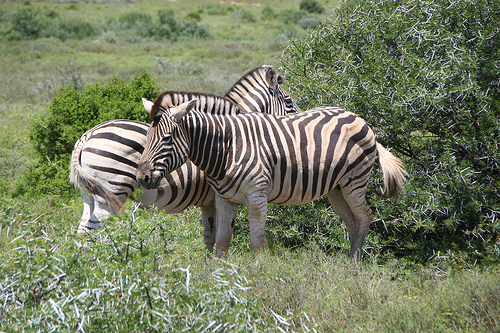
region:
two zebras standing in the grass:
[63, 52, 404, 272]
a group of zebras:
[61, 40, 436, 280]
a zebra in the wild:
[135, 95, 410, 270]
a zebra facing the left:
[135, 95, 425, 272]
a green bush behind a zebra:
[7, 45, 177, 215]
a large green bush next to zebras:
[255, 5, 490, 277]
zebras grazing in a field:
[56, 70, 401, 310]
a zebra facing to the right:
[57, 60, 302, 256]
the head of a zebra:
[129, 96, 193, 202]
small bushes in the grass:
[9, 1, 259, 51]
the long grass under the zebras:
[1, 201, 231, 330]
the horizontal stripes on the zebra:
[187, 113, 347, 191]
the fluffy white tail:
[374, 142, 409, 194]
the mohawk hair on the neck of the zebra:
[147, 90, 239, 125]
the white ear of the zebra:
[171, 97, 200, 117]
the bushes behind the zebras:
[290, 0, 492, 104]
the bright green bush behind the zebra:
[39, 67, 134, 117]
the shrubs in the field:
[14, 4, 326, 40]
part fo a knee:
[358, 217, 375, 234]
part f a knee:
[221, 201, 227, 261]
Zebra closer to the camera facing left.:
[139, 103, 378, 261]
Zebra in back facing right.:
[63, 69, 310, 249]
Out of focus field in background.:
[2, 2, 334, 159]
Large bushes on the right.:
[276, 4, 498, 251]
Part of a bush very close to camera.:
[3, 228, 292, 328]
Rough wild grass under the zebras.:
[21, 204, 491, 329]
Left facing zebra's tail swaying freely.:
[371, 135, 406, 204]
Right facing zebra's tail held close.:
[58, 130, 120, 212]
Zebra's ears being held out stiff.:
[133, 93, 199, 123]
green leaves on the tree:
[365, 70, 435, 143]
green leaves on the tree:
[405, 182, 445, 225]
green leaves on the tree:
[415, 100, 440, 141]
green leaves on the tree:
[440, 33, 476, 126]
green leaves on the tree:
[370, 10, 456, 112]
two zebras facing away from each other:
[68, 64, 411, 260]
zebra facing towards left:
[135, 89, 412, 260]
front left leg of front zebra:
[245, 175, 270, 254]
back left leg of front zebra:
[339, 169, 373, 256]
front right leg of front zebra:
[212, 191, 239, 255]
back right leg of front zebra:
[326, 183, 359, 255]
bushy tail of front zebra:
[374, 140, 412, 199]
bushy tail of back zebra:
[68, 140, 123, 215]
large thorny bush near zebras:
[230, 0, 498, 265]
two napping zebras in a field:
[66, 65, 406, 260]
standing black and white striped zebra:
[136, 87, 407, 262]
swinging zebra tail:
[375, 138, 409, 203]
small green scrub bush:
[30, 69, 155, 159]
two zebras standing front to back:
[67, 62, 410, 260]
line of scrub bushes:
[1, 2, 213, 44]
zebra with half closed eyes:
[134, 88, 411, 261]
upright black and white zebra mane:
[147, 91, 241, 121]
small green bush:
[12, 158, 69, 193]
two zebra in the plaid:
[71, 53, 405, 254]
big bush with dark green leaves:
[279, 9, 499, 254]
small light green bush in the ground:
[11, 70, 164, 208]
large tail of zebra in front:
[371, 140, 406, 196]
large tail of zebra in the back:
[71, 145, 125, 233]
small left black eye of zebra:
[160, 128, 170, 153]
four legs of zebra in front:
[211, 190, 371, 260]